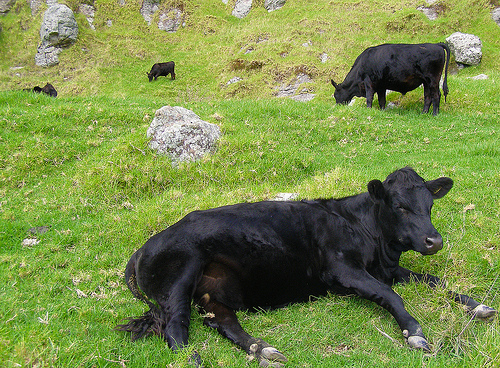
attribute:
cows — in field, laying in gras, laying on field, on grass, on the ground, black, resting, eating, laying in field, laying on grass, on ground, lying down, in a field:
[117, 163, 495, 359]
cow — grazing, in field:
[144, 57, 177, 83]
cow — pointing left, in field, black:
[329, 29, 448, 118]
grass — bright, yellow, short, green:
[8, 100, 129, 175]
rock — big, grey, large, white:
[144, 106, 225, 165]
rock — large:
[37, 4, 83, 63]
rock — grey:
[439, 30, 484, 68]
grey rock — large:
[142, 1, 193, 32]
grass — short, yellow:
[78, 37, 161, 67]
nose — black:
[417, 235, 443, 250]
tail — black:
[445, 45, 452, 99]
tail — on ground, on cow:
[123, 271, 162, 344]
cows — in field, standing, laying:
[4, 6, 492, 367]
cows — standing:
[137, 44, 453, 120]